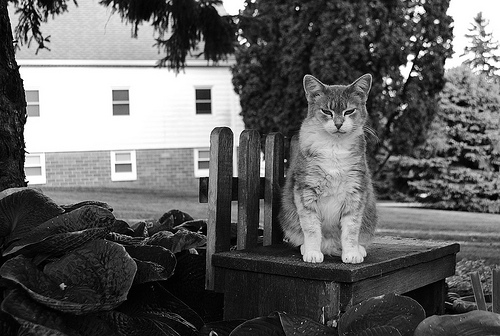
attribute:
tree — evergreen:
[0, 4, 257, 199]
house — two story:
[12, 0, 309, 250]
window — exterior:
[113, 86, 131, 118]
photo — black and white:
[1, 2, 497, 334]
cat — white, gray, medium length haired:
[282, 73, 406, 257]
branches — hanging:
[7, 1, 242, 74]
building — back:
[1, 4, 281, 271]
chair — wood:
[195, 125, 460, 327]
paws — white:
[298, 245, 368, 265]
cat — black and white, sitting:
[278, 72, 376, 264]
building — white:
[9, 12, 289, 193]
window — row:
[23, 88, 42, 118]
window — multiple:
[24, 89, 41, 116]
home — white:
[1, 0, 266, 197]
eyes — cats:
[325, 108, 357, 117]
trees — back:
[288, 3, 495, 72]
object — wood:
[198, 156, 292, 295]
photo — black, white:
[42, 37, 472, 307]